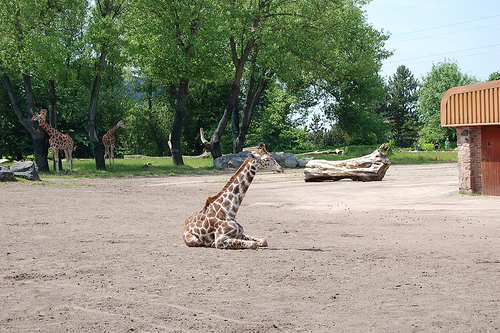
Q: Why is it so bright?
A: Day time.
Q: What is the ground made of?
A: Dirt.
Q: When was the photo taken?
A: Morning.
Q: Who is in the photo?
A: Giraffes.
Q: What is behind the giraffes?
A: Trees.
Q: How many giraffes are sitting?
A: One.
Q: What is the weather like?
A: Sunny.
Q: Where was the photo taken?
A: At the zoo.